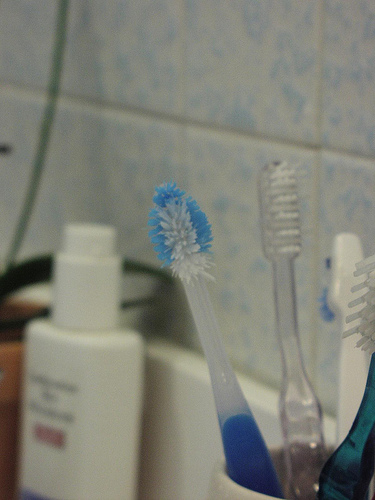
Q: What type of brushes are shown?
A: Toothbrushes.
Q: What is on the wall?
A: Tile.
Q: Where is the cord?
A: Left side of the image.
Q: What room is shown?
A: Bathroom.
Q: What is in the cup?
A: Toothbrushes.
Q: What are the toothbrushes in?
A: Cup.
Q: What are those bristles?
A: Old blue toothbrush.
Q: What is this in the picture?
A: A clear and white toothbrush.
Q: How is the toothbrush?
A: White and blue.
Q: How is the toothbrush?
A: Transparent blue and white.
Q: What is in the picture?
A: A white spray bottle.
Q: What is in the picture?
A: A blue speckled white tile.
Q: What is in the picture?
A: A blue speckled white tile.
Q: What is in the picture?
A: A blue speckled white tile.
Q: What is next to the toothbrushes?
A: A bottle.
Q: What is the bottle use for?
A: Lotion.